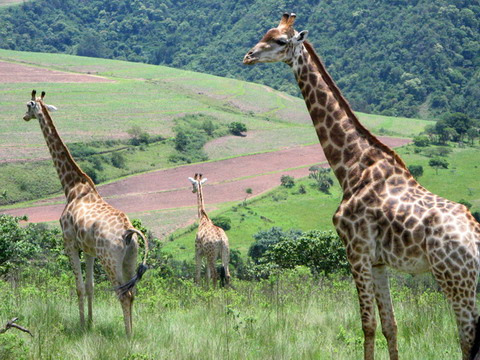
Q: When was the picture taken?
A: Daytime.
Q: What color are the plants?
A: Green.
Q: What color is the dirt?
A: Brown.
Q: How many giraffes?
A: Three.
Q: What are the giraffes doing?
A: Standing.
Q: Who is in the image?
A: Giraffes.